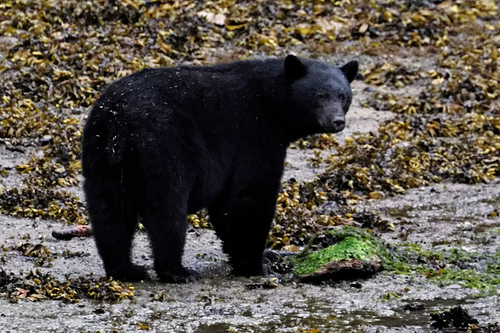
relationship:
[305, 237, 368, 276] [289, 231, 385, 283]
moss attached to rock